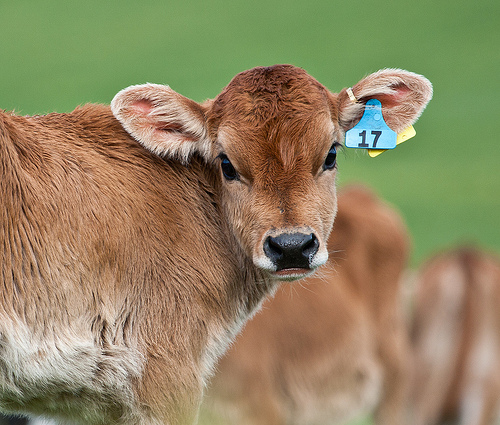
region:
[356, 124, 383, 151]
The number 17 in black on blue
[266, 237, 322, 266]
A black and shiny animal nose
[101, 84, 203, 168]
An animal's right ear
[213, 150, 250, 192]
A black animal eye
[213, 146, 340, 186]
An animal's two eyes staring forward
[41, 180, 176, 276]
A patch of brown animal fur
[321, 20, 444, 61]
A green featureless background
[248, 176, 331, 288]
An animal's snout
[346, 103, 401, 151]
A blue plastic tag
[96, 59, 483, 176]
Two animal ears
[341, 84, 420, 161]
tag on the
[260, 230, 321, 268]
black small nose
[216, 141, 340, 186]
the beady eyes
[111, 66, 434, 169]
the fluffy ears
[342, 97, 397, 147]
blue tag says 17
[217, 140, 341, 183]
calf's eyes are looking at the camera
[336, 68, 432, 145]
calf's left ear is tagged.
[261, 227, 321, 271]
calf's nose is black